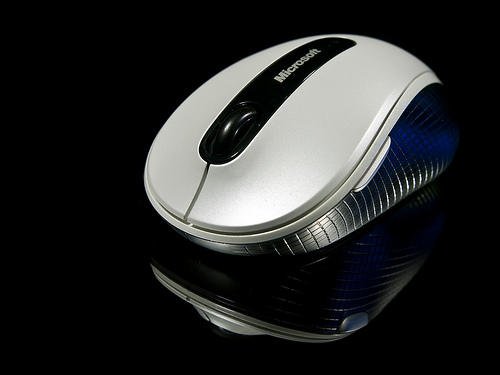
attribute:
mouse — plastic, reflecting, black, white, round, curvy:
[124, 25, 482, 263]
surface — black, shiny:
[5, 104, 500, 340]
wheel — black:
[197, 102, 278, 161]